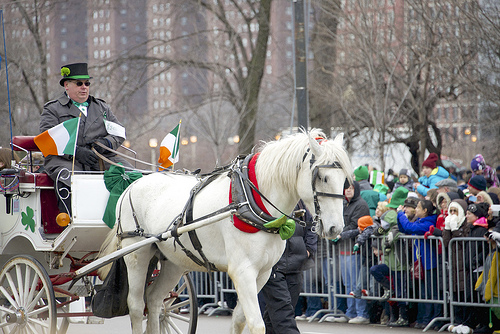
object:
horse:
[91, 125, 357, 331]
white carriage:
[0, 169, 199, 332]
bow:
[266, 215, 296, 240]